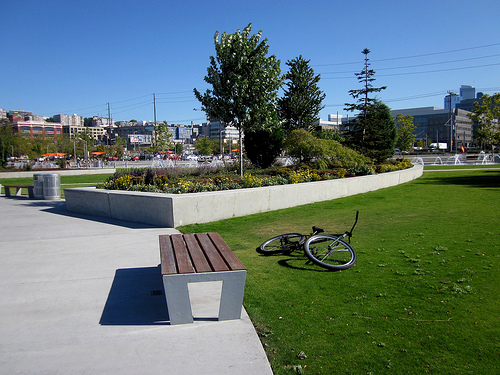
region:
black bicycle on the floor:
[255, 216, 363, 274]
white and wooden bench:
[152, 229, 242, 327]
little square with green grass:
[2, 163, 490, 368]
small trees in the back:
[190, 32, 407, 176]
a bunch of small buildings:
[1, 101, 488, 159]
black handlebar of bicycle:
[345, 211, 366, 245]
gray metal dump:
[30, 169, 70, 200]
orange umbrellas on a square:
[36, 144, 246, 172]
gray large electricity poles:
[52, 35, 494, 150]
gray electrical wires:
[84, 32, 491, 126]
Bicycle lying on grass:
[255, 205, 364, 275]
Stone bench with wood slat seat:
[157, 228, 222, 320]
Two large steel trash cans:
[29, 169, 60, 204]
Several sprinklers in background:
[412, 154, 489, 169]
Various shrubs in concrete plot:
[126, 144, 381, 205]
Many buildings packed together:
[15, 115, 143, 139]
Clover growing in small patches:
[370, 236, 448, 310]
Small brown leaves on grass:
[377, 302, 422, 343]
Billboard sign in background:
[127, 135, 146, 144]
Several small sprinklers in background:
[145, 153, 217, 172]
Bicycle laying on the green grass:
[253, 211, 370, 270]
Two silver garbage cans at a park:
[28, 169, 63, 199]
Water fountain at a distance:
[429, 149, 499, 166]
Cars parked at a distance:
[113, 148, 218, 163]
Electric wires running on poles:
[66, 90, 206, 117]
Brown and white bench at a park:
[148, 227, 250, 325]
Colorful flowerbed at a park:
[103, 165, 265, 195]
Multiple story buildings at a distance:
[410, 97, 499, 154]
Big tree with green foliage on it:
[201, 25, 274, 183]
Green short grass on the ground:
[314, 282, 460, 357]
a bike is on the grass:
[248, 177, 378, 286]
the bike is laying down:
[252, 203, 386, 293]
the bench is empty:
[149, 197, 265, 329]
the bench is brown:
[138, 220, 245, 278]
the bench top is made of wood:
[150, 227, 242, 276]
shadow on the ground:
[90, 242, 177, 334]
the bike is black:
[237, 196, 379, 290]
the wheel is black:
[300, 231, 367, 287]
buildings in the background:
[10, 87, 242, 154]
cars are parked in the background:
[132, 139, 217, 171]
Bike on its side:
[256, 208, 368, 273]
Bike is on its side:
[257, 208, 369, 274]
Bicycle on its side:
[256, 207, 368, 277]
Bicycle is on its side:
[255, 202, 367, 275]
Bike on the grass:
[255, 205, 367, 274]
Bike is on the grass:
[257, 205, 362, 274]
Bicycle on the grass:
[255, 206, 365, 273]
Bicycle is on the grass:
[255, 207, 365, 274]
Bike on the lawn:
[255, 207, 375, 274]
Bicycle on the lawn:
[250, 202, 379, 278]